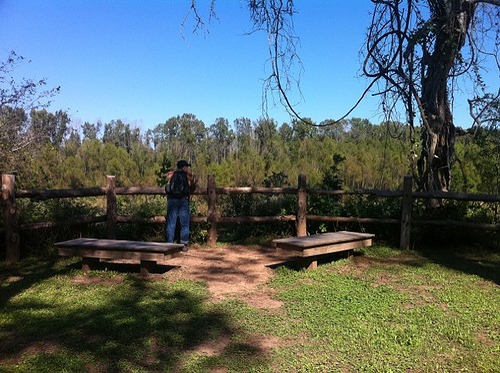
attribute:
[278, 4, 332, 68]
sky — blue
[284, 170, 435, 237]
donut — wooden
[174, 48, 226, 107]
clouds — white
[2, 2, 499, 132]
sky — blue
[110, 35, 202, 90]
sky — blue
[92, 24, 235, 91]
sky — blue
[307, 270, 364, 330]
grass — green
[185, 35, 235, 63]
clouds — white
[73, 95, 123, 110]
clouds — white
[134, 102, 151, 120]
clouds — white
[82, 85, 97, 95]
clouds — white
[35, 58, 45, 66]
clouds — white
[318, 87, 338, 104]
clouds — white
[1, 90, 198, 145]
clouds — white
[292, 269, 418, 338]
grass — short , green 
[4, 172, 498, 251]
fence — brown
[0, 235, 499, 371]
grass — green, short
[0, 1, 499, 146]
sky — blue